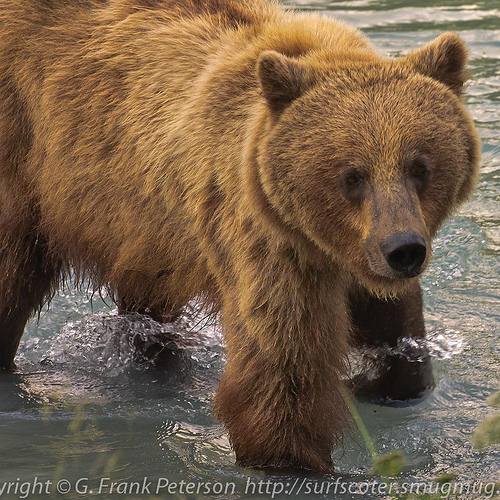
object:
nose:
[387, 243, 426, 275]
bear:
[1, 0, 481, 475]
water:
[425, 223, 499, 499]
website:
[244, 475, 499, 499]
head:
[258, 32, 477, 299]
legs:
[0, 237, 62, 375]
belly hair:
[49, 236, 215, 319]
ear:
[258, 50, 321, 112]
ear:
[406, 31, 467, 87]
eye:
[343, 172, 362, 186]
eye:
[410, 163, 428, 177]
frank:
[99, 478, 152, 496]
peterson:
[156, 478, 237, 495]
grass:
[37, 389, 126, 474]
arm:
[223, 274, 342, 477]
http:
[246, 478, 283, 498]